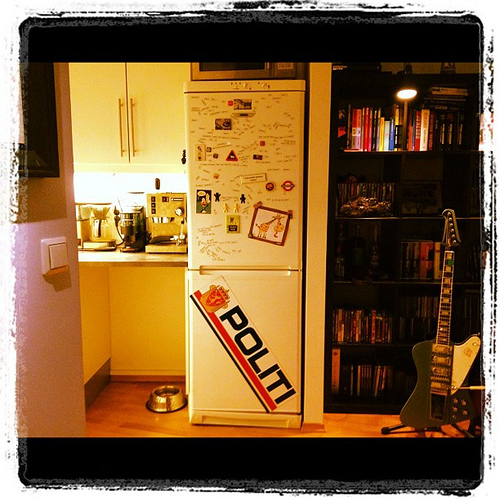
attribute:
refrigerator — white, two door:
[176, 76, 310, 431]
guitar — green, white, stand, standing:
[393, 203, 484, 439]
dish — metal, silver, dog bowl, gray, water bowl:
[140, 379, 188, 416]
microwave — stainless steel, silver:
[184, 60, 312, 82]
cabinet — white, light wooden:
[74, 67, 194, 171]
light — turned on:
[390, 69, 419, 102]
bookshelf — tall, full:
[328, 68, 487, 413]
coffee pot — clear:
[111, 188, 154, 254]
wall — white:
[24, 65, 89, 442]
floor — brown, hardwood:
[95, 377, 150, 435]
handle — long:
[124, 93, 136, 168]